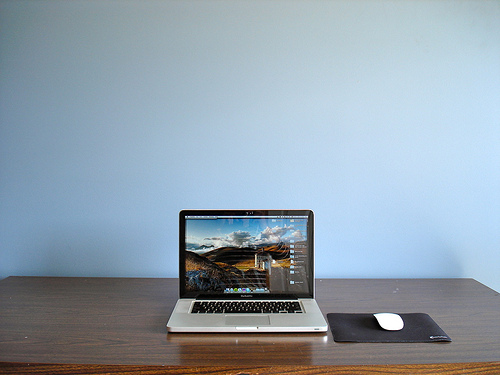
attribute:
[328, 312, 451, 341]
mouse pad — black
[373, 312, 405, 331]
computer mouse — white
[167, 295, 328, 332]
keyboard — black, gray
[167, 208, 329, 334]
laptop computer — open, displayed, on, turned on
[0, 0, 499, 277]
wall — clear, blue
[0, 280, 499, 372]
desk — brown, wooden, made of wood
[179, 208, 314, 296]
monitor — framed